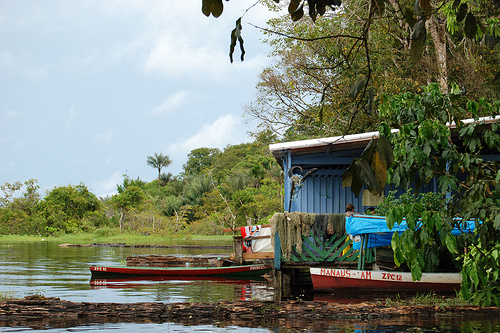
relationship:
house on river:
[263, 140, 386, 214] [9, 246, 65, 287]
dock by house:
[237, 219, 291, 257] [263, 140, 386, 214]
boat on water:
[79, 235, 243, 300] [210, 282, 224, 294]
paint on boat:
[315, 278, 321, 298] [79, 235, 243, 300]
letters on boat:
[353, 261, 394, 280] [79, 235, 243, 300]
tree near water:
[370, 50, 443, 129] [210, 282, 224, 294]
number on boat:
[380, 274, 395, 282] [79, 235, 243, 300]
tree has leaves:
[370, 50, 443, 129] [272, 51, 334, 91]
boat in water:
[79, 235, 243, 300] [210, 282, 224, 294]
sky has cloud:
[98, 35, 137, 74] [80, 107, 128, 145]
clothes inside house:
[283, 205, 375, 243] [263, 140, 386, 214]